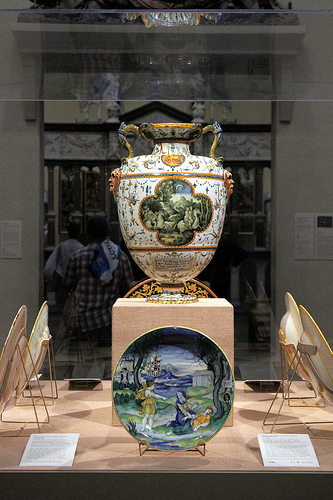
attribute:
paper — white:
[253, 430, 320, 469]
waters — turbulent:
[146, 371, 190, 391]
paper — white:
[19, 432, 79, 466]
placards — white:
[16, 424, 78, 467]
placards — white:
[253, 423, 323, 470]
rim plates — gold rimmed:
[296, 303, 332, 395]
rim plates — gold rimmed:
[277, 288, 306, 387]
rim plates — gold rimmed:
[14, 299, 52, 395]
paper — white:
[253, 424, 324, 468]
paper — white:
[17, 428, 81, 470]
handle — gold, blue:
[196, 119, 225, 159]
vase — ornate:
[106, 112, 240, 307]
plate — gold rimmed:
[296, 303, 332, 380]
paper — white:
[6, 428, 81, 470]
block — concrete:
[112, 295, 236, 428]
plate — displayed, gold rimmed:
[110, 323, 235, 455]